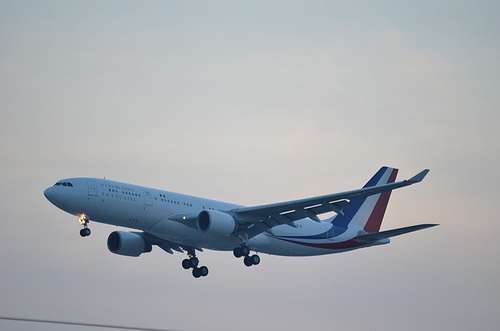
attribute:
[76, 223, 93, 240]
wheels — small, landing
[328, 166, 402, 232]
tail — blue, red, white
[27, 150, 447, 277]
airplane — white, blue, Red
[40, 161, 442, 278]
plane — white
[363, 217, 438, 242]
back wing — small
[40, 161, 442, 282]
airplane — red, white, blue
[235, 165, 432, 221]
wing — white, large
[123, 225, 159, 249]
wing — white, large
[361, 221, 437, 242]
wing — white, large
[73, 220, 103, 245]
wheels — small, black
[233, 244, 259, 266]
wheels — landing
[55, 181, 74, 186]
window — small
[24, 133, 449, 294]
airplane — white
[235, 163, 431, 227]
wing — long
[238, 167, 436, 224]
wing — large, one, white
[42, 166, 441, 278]
jet — large, blue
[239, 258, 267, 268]
back wheel — black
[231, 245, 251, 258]
back wheel — black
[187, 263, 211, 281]
back wheel — black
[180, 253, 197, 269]
back wheel — black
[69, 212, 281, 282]
gear — landing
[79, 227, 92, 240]
wheel — black, small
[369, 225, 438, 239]
back wing — small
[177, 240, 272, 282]
wheels — black, white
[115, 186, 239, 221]
windows — tiny, white